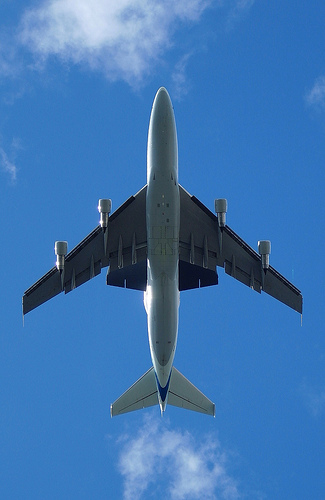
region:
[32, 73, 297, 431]
plane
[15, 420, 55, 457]
white clouds in blue sky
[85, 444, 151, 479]
white clouds in blue sky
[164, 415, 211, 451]
white clouds in blue sky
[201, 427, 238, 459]
white clouds in blue sky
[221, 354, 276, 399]
white clouds in blue sky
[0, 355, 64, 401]
white clouds in blue sky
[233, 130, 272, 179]
white clouds in blue sky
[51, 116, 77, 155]
white clouds in blue sky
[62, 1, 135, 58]
white clouds in blue sky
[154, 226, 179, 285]
this is an airplane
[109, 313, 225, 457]
this is a tail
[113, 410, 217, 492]
this is a cloud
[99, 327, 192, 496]
the cloud is white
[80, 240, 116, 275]
this is a wing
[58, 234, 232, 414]
there are two wings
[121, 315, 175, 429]
the tail has blue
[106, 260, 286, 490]
the plane is long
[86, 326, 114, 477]
there are no birds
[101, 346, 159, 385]
the plane is steel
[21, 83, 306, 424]
the bottom of an airplane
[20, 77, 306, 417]
an airplane in the air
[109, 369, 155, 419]
the tail wing of an airplane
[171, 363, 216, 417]
the tail wing of an airplane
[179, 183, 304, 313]
the wing of a plane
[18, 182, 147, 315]
the wing of a plane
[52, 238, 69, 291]
an engine of an airplane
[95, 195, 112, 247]
an engine of an airplane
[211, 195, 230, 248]
an engine of an airplane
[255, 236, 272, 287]
an engine of an airplane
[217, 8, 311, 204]
the sky is blue and clear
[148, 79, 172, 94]
the nose of the plane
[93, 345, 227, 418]
the tail of the plane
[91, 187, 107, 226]
the engine of the plane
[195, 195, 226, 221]
the engine of the plane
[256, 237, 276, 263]
the engine of the plane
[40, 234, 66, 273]
the engine of the plane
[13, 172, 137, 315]
the wing of the plane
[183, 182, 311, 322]
the wing of the plane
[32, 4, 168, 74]
clouds in the sky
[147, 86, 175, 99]
nose of big plane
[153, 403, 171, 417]
point of plane tail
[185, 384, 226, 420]
right side of tail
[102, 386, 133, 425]
left side of tail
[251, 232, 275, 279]
first propeller on right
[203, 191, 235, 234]
second propeller on right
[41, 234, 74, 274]
first propeller on left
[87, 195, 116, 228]
second propeller on left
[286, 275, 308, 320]
wing on right of plane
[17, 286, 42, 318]
wing on left of plane